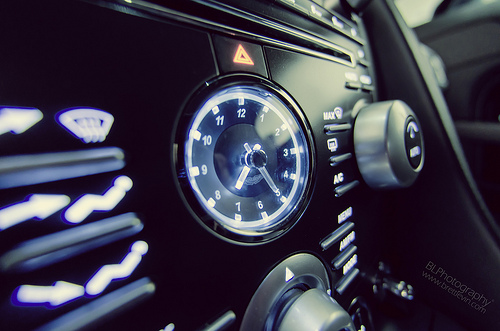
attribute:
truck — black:
[16, 14, 486, 285]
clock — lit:
[171, 75, 316, 240]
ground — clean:
[396, 152, 454, 191]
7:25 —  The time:
[226, 136, 298, 247]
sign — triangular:
[226, 39, 263, 66]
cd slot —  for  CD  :
[134, 0, 357, 66]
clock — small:
[158, 67, 320, 248]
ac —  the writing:
[315, 156, 362, 211]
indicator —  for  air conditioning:
[333, 177, 361, 202]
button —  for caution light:
[208, 29, 278, 76]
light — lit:
[208, 30, 285, 96]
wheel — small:
[352, 91, 429, 190]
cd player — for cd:
[131, 7, 355, 68]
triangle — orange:
[217, 36, 267, 72]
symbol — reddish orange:
[229, 42, 254, 67]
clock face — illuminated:
[166, 63, 324, 250]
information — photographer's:
[419, 260, 499, 315]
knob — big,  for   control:
[351, 99, 428, 189]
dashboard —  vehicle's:
[2, 2, 499, 328]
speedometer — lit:
[182, 83, 307, 234]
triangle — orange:
[232, 39, 262, 71]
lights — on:
[1, 8, 453, 326]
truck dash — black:
[1, 8, 499, 320]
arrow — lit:
[2, 181, 69, 242]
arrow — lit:
[4, 92, 47, 157]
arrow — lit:
[15, 270, 82, 313]